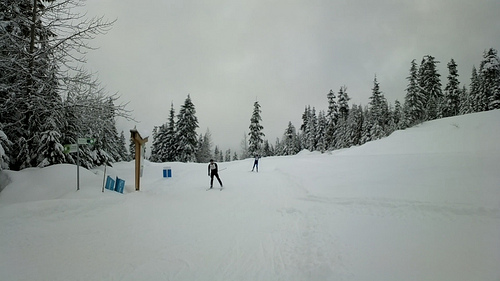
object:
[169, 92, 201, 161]
tree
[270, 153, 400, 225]
snow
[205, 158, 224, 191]
person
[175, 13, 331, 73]
sky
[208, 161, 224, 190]
clothing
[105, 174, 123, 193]
objects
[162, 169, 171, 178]
objects